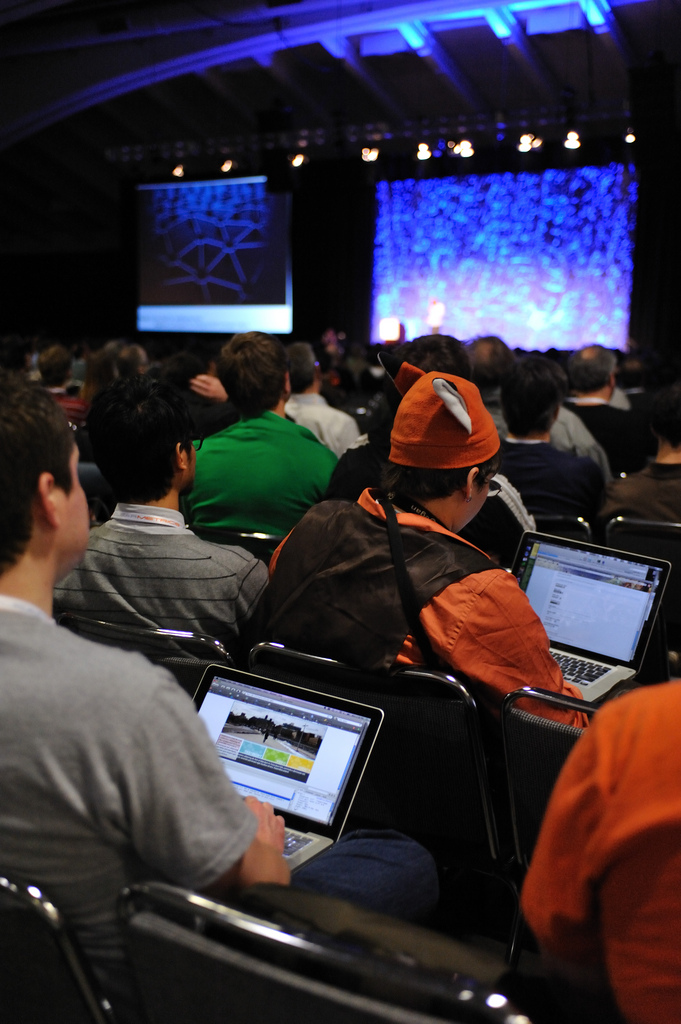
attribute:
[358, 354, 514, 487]
hat — brown, orange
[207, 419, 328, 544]
polo shirt — green